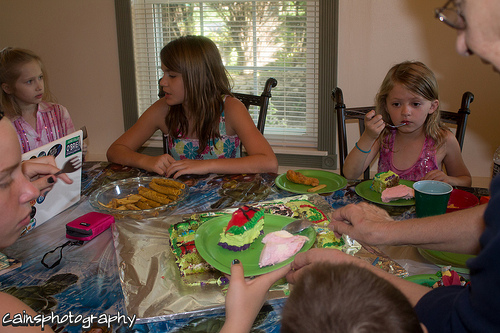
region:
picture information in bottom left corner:
[5, 310, 147, 328]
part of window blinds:
[250, 23, 302, 63]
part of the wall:
[355, 17, 420, 47]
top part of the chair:
[266, 77, 279, 101]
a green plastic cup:
[420, 182, 442, 208]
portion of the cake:
[231, 199, 258, 252]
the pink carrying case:
[56, 214, 106, 234]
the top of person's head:
[322, 285, 389, 323]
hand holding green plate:
[223, 261, 266, 305]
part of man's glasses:
[437, 14, 463, 32]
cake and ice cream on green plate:
[202, 197, 313, 279]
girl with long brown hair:
[140, 52, 254, 200]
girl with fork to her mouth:
[365, 65, 423, 142]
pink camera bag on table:
[41, 192, 135, 282]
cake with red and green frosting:
[218, 201, 268, 255]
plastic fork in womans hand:
[17, 125, 97, 207]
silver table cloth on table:
[1, 165, 258, 319]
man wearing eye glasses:
[427, 5, 497, 66]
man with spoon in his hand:
[274, 194, 395, 246]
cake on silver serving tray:
[111, 222, 293, 326]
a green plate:
[188, 190, 303, 321]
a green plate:
[168, 145, 338, 328]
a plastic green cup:
[407, 178, 452, 217]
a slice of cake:
[215, 202, 268, 251]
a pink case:
[33, 209, 116, 269]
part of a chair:
[227, 76, 279, 134]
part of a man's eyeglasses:
[422, 1, 468, 30]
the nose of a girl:
[15, 175, 44, 203]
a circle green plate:
[277, 167, 346, 193]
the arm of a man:
[312, 202, 498, 250]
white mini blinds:
[129, 1, 321, 151]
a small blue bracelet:
[353, 135, 374, 158]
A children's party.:
[5, 35, 487, 320]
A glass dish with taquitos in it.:
[90, 171, 180, 211]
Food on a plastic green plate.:
[190, 210, 320, 277]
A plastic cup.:
[410, 175, 450, 215]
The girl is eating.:
[330, 61, 485, 186]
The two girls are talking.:
[0, 30, 262, 150]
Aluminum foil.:
[115, 226, 175, 311]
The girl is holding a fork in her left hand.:
[0, 90, 100, 251]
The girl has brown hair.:
[155, 30, 240, 145]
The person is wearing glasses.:
[426, 0, 496, 90]